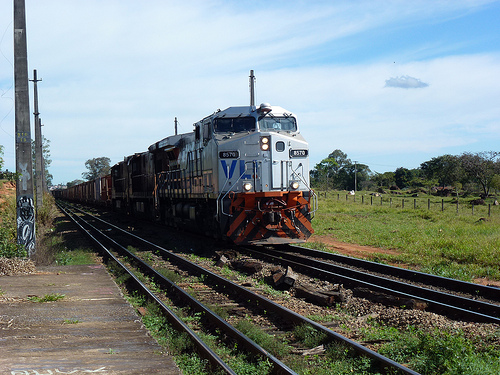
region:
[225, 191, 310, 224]
the front of the train is black and orange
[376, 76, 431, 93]
the cloud is in the sky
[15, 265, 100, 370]
the platform is brown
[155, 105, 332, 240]
the train is coming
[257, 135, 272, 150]
the lights are on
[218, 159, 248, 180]
the letters are blue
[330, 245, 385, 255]
the dirt is brown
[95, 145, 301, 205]
the train is large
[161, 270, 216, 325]
there are 3 lines of the track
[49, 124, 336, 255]
the train is long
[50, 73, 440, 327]
a train on the railroad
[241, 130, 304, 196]
lights on front of train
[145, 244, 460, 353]
rails are covered wods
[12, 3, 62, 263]
poles on left side of train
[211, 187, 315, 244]
bumper of train is red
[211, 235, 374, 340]
pieces of wood on railroad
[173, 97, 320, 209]
front car of train is white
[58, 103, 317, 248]
this is a freight train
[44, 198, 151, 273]
shadow cast on the ground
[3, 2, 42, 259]
a wood pole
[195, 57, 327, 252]
Front end of a cargo train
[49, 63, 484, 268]
Cargo train passing through a rural area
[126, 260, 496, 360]
Double train tracks surrounded by grass and gravel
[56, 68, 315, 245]
Long cargo train as seen from the front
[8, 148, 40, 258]
Grafitti written on a telephone pole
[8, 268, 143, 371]
Grass popping through old wooden planking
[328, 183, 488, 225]
Fencing with wooden poles in a grassy field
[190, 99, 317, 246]
Front end of a cargo train with black and orange stripes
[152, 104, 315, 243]
Caboose of a modern cargo train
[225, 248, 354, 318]
Pile of wood inbetween train tracks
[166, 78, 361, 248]
front of the train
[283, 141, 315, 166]
number on front of train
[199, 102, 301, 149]
window on front of train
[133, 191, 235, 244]
bottom part of the train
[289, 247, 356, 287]
track under the train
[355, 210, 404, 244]
grass next to train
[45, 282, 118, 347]
cement next to tracks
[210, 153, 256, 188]
blue writing on the train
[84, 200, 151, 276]
shadow on the ground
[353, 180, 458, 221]
fence in the background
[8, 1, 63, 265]
Three electric line poles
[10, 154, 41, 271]
Graffiti painted on electricity pole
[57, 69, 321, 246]
Many car freight train on track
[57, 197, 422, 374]
Metal railroad track with weeds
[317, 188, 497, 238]
Wood and wire fencing in field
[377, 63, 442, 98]
Small gray cloud in sky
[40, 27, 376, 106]
Wispy white clouds in light blue sky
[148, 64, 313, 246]
Gray conductor train car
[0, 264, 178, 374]
Wooden train platform with weeds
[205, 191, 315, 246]
Red and black striped paint on train car